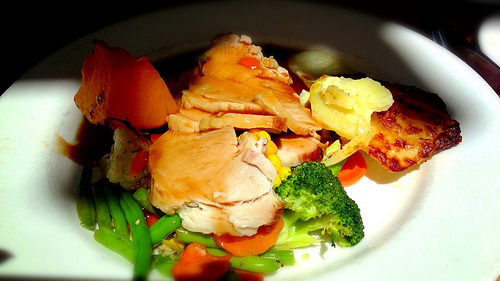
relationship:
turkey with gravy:
[151, 138, 290, 231] [67, 120, 108, 154]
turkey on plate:
[151, 138, 290, 231] [4, 2, 498, 279]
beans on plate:
[73, 179, 155, 280] [4, 2, 498, 279]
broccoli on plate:
[277, 167, 368, 246] [4, 2, 498, 279]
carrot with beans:
[70, 40, 176, 135] [73, 179, 155, 280]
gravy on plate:
[67, 120, 108, 154] [4, 2, 498, 279]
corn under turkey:
[250, 131, 292, 180] [151, 138, 290, 231]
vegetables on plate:
[49, 43, 176, 280] [4, 2, 498, 279]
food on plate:
[77, 38, 437, 277] [4, 2, 498, 279]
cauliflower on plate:
[95, 131, 144, 186] [4, 2, 498, 279]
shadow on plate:
[40, 5, 400, 59] [4, 2, 498, 279]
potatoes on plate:
[349, 74, 460, 174] [4, 2, 498, 279]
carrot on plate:
[70, 40, 176, 135] [4, 2, 498, 279]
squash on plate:
[285, 46, 342, 80] [4, 2, 498, 279]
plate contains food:
[4, 2, 498, 279] [77, 38, 437, 277]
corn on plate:
[250, 131, 292, 180] [4, 2, 498, 279]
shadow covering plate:
[40, 5, 400, 59] [4, 2, 498, 279]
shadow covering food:
[40, 5, 400, 59] [77, 38, 437, 277]